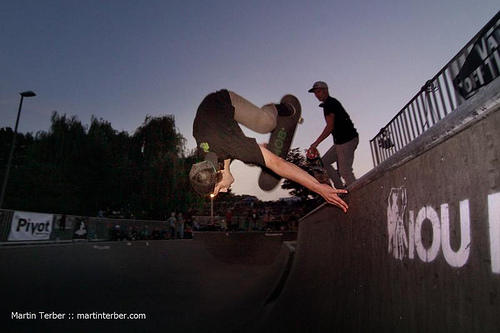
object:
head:
[189, 158, 236, 196]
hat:
[189, 152, 218, 197]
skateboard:
[258, 93, 305, 192]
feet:
[268, 102, 297, 118]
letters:
[409, 210, 415, 261]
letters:
[414, 207, 441, 263]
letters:
[441, 199, 470, 268]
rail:
[369, 10, 498, 169]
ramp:
[0, 88, 497, 333]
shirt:
[318, 96, 359, 145]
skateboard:
[304, 148, 330, 184]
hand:
[305, 143, 320, 159]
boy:
[189, 87, 349, 213]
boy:
[306, 80, 360, 190]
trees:
[0, 110, 183, 217]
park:
[4, 211, 146, 333]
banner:
[8, 211, 55, 242]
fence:
[0, 208, 171, 246]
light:
[19, 90, 36, 97]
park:
[226, 152, 469, 330]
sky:
[1, 3, 494, 199]